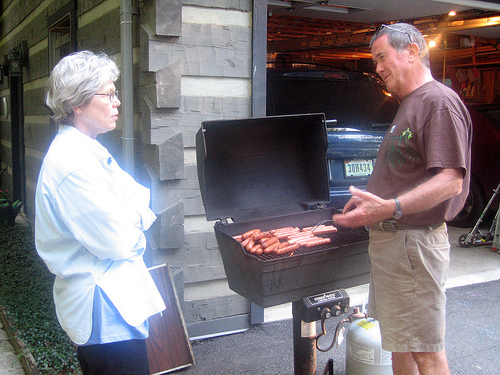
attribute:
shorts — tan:
[404, 254, 449, 344]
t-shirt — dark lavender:
[375, 134, 494, 176]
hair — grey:
[394, 50, 409, 71]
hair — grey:
[58, 50, 94, 105]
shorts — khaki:
[396, 267, 446, 344]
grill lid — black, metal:
[193, 110, 333, 225]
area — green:
[1, 220, 82, 372]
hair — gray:
[365, 21, 432, 70]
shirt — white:
[32, 120, 167, 347]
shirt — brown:
[365, 76, 475, 227]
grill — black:
[194, 109, 371, 373]